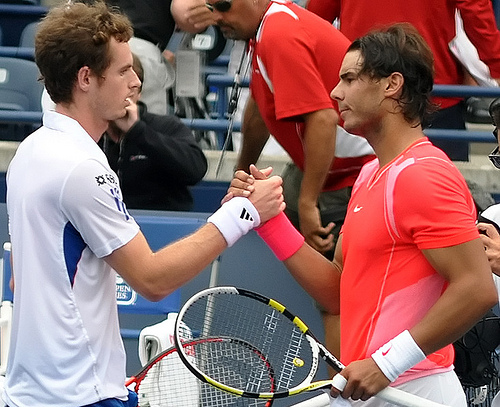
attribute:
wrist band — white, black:
[207, 196, 260, 248]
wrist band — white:
[371, 328, 426, 383]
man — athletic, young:
[219, 22, 499, 406]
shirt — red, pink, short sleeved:
[337, 136, 481, 387]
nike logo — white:
[353, 204, 363, 212]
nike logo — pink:
[381, 343, 391, 356]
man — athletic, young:
[4, 0, 286, 406]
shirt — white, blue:
[4, 109, 141, 406]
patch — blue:
[64, 221, 88, 291]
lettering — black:
[94, 174, 118, 187]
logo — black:
[239, 207, 255, 222]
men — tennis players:
[0, 0, 499, 406]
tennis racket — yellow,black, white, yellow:
[174, 285, 451, 406]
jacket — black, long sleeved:
[97, 101, 208, 212]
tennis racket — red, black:
[125, 335, 276, 406]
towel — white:
[139, 312, 200, 406]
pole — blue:
[0, 109, 497, 142]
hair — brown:
[34, 0, 133, 109]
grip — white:
[372, 384, 450, 406]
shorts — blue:
[81, 388, 137, 405]